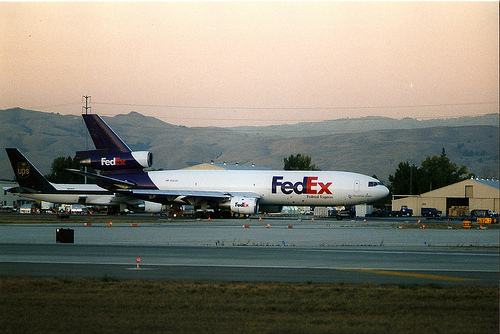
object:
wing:
[4, 146, 57, 193]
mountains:
[0, 105, 499, 181]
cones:
[264, 223, 270, 228]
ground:
[0, 214, 499, 333]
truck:
[387, 204, 413, 219]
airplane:
[0, 147, 206, 214]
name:
[267, 174, 331, 197]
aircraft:
[55, 113, 392, 218]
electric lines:
[26, 97, 499, 112]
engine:
[85, 150, 154, 169]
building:
[390, 175, 500, 219]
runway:
[0, 217, 498, 285]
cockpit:
[364, 181, 386, 188]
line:
[343, 267, 468, 283]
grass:
[0, 275, 499, 334]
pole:
[80, 92, 90, 183]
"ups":
[17, 167, 30, 178]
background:
[0, 0, 499, 333]